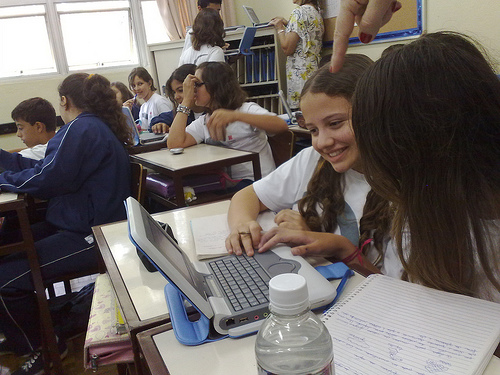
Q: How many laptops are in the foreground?
A: One.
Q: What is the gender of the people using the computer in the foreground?
A: Female.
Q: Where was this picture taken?
A: A school.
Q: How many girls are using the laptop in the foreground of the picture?
A: Two.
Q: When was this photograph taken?
A: Daytime.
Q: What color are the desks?
A: White.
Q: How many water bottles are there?
A: One.